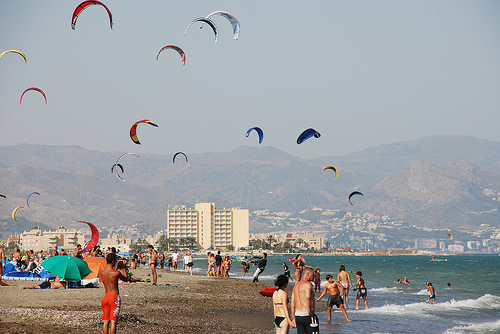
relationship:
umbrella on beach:
[38, 252, 94, 285] [3, 247, 353, 333]